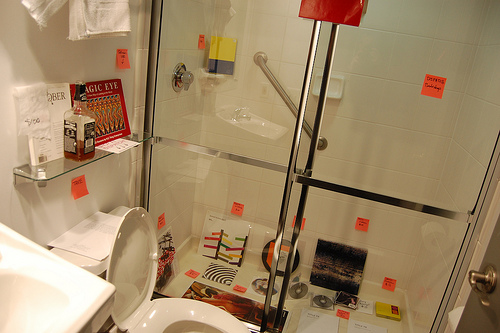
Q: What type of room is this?
A: Bathroom.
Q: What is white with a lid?
A: Toilet.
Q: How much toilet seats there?
A: One.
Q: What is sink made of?
A: Porcelein.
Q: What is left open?
A: Toilet seat?.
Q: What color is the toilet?
A: White.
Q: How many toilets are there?
A: One.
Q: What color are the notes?
A: Red.